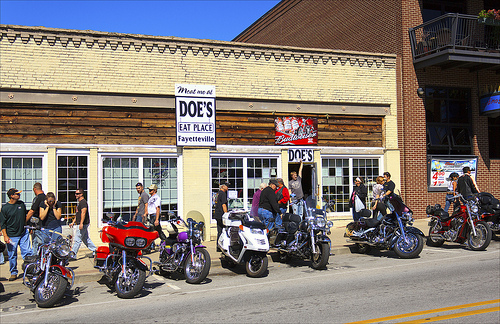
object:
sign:
[174, 83, 219, 149]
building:
[0, 24, 403, 249]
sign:
[274, 114, 321, 146]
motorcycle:
[426, 193, 491, 251]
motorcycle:
[87, 213, 161, 299]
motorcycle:
[344, 190, 430, 259]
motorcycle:
[272, 194, 332, 271]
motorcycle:
[155, 212, 212, 284]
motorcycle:
[25, 222, 77, 309]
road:
[5, 232, 499, 322]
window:
[101, 153, 180, 222]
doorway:
[289, 161, 317, 230]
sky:
[1, 1, 281, 43]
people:
[2, 181, 64, 281]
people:
[249, 158, 309, 245]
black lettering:
[178, 100, 214, 146]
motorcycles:
[94, 191, 429, 297]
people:
[129, 181, 168, 241]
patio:
[407, 13, 499, 74]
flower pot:
[477, 9, 499, 25]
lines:
[346, 299, 498, 324]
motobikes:
[215, 199, 334, 277]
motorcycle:
[215, 208, 271, 277]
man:
[145, 184, 171, 248]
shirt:
[145, 194, 162, 217]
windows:
[212, 154, 391, 218]